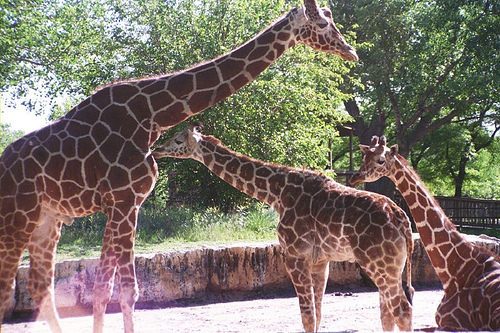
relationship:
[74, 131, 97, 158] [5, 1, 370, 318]
spot on giraffe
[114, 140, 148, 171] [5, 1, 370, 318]
spot on giraffe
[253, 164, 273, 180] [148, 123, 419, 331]
spot on giraffe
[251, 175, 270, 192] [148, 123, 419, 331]
spot on giraffe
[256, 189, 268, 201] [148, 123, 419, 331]
spot on giraffe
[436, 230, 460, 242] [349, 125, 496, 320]
brown spot on giraffe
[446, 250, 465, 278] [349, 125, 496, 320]
brown spot on giraffe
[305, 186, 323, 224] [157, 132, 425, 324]
brown spot on giraffe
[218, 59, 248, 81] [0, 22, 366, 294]
brown spot on giraffe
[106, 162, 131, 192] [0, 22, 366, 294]
brown spot on giraffe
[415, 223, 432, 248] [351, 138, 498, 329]
spot on giraffe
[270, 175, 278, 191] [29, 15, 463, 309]
brown spot on giraffe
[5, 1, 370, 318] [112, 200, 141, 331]
giraffe has leg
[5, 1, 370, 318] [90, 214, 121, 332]
giraffe has leg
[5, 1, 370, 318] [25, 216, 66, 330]
giraffe has leg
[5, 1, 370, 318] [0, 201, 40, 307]
giraffe has leg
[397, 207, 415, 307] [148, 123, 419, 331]
tail of a giraffe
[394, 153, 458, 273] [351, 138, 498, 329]
neck of a giraffe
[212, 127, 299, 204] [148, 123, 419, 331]
neck of a giraffe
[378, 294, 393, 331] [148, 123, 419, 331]
leg of a giraffe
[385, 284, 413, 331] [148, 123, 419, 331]
leg of a giraffe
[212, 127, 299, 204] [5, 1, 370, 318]
neck of a giraffe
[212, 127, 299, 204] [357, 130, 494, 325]
neck of a giraffe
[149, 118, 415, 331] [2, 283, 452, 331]
giraffes in field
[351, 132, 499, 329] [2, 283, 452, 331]
giraffes in field